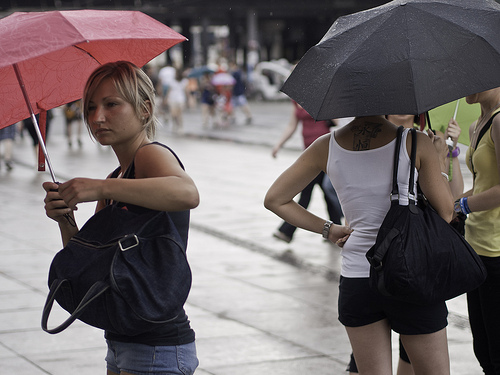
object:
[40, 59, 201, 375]
person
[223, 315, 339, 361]
line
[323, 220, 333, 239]
watch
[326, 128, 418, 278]
white tank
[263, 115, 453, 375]
woman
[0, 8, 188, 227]
umbrella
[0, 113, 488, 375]
pavement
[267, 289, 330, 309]
line